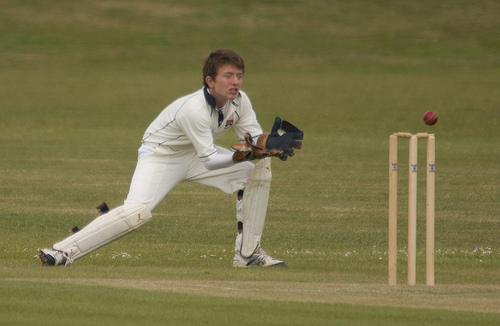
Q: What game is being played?
A: Cricket.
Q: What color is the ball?
A: Red.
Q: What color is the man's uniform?
A: White.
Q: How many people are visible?
A: One.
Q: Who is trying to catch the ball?
A: Player.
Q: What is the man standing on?
A: Grass.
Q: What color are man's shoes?
A: White.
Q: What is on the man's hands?
A: Gloves to catch with.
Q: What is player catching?
A: A red ball.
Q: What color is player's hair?
A: Brown.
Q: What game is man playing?
A: Cricket.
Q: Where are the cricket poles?
A: On right side.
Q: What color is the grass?
A: Green.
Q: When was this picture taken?
A: Daytime.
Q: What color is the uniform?
A: White.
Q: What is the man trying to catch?
A: A ball.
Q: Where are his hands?
A: In front of him.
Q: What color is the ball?
A: Red.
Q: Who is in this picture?
A: A man.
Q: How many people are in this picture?
A: One.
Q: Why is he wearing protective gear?
A: Safety.